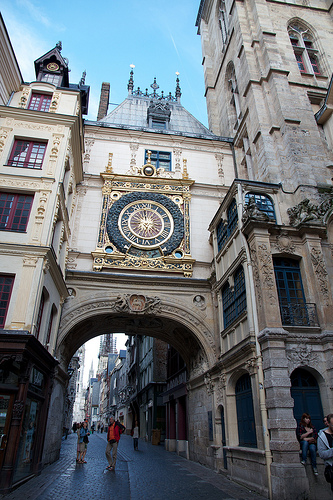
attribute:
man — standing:
[102, 413, 132, 476]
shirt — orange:
[107, 424, 124, 443]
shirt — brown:
[77, 426, 94, 442]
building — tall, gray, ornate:
[1, 36, 325, 431]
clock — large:
[98, 184, 195, 260]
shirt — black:
[321, 434, 332, 470]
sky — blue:
[3, 8, 231, 93]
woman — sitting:
[298, 419, 325, 471]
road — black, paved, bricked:
[43, 422, 182, 499]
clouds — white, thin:
[11, 27, 64, 81]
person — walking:
[129, 426, 146, 454]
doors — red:
[156, 393, 199, 460]